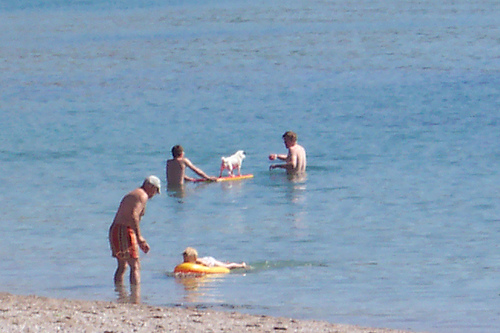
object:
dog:
[216, 148, 247, 176]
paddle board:
[210, 172, 250, 183]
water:
[2, 5, 495, 330]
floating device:
[173, 260, 232, 278]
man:
[102, 174, 165, 301]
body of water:
[163, 157, 186, 192]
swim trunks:
[105, 222, 147, 262]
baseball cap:
[143, 175, 165, 192]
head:
[142, 173, 162, 199]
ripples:
[0, 2, 499, 75]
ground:
[1, 288, 409, 332]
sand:
[0, 294, 417, 333]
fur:
[226, 158, 236, 165]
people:
[163, 142, 216, 186]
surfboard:
[203, 171, 253, 185]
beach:
[0, 293, 426, 332]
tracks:
[0, 291, 403, 332]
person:
[267, 127, 309, 181]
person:
[180, 246, 250, 271]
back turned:
[164, 160, 181, 190]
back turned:
[290, 146, 308, 171]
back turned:
[112, 186, 146, 227]